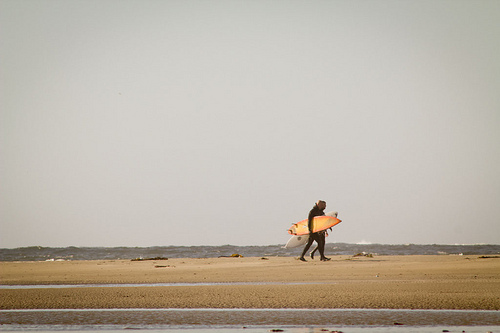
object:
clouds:
[0, 0, 76, 67]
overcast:
[46, 80, 162, 193]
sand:
[1, 255, 498, 307]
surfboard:
[286, 215, 343, 236]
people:
[299, 199, 332, 262]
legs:
[298, 231, 330, 262]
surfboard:
[283, 210, 340, 250]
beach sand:
[12, 260, 499, 332]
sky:
[0, 0, 498, 180]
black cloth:
[298, 205, 330, 262]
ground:
[22, 281, 423, 307]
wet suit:
[299, 203, 328, 262]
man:
[298, 200, 328, 263]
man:
[309, 226, 332, 261]